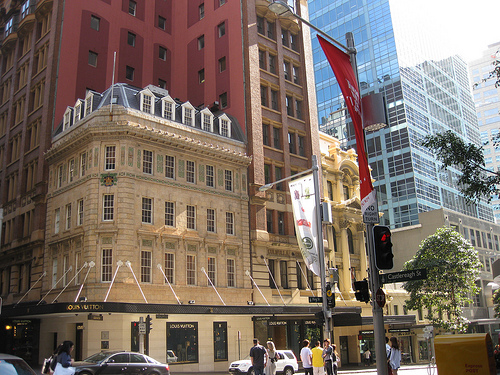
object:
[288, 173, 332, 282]
banner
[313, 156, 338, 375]
pole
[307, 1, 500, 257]
building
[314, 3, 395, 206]
glass